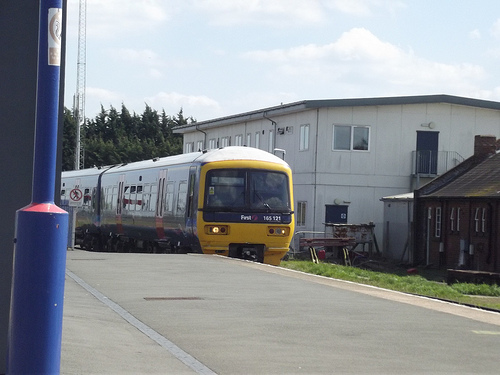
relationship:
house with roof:
[413, 186, 499, 268] [413, 149, 499, 198]